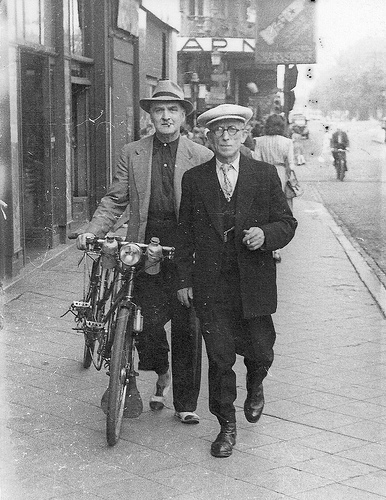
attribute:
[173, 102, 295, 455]
man — elderly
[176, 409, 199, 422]
shoes — black and white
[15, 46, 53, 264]
door — open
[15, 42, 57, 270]
trim — wooden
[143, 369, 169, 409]
shoes — two toned, mens shoes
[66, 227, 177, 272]
handle bars — bicycle handle bars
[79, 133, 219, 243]
jacket — suit jacket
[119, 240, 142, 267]
headlight — chrome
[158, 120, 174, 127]
mouth — man's mouth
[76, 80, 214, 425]
man — elderly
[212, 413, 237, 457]
boot — black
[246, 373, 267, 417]
boot — black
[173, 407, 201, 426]
shoe — black, white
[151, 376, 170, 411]
shoe — black, white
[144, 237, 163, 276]
bottle — metal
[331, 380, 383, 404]
tile — square tile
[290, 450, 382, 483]
tile — square tile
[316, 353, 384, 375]
tile — square tile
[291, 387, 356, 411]
tile — square tile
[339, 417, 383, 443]
tile — square tile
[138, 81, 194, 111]
hat — fedora hat